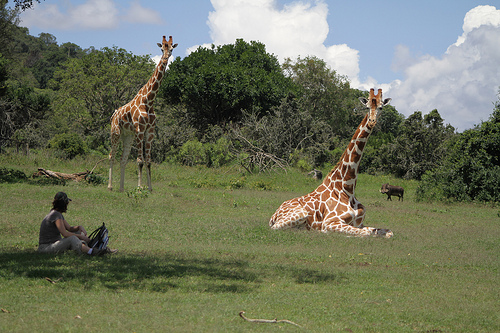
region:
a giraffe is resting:
[263, 83, 398, 265]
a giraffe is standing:
[84, 35, 181, 197]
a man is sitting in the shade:
[31, 182, 112, 271]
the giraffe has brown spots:
[241, 77, 388, 243]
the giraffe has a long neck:
[275, 83, 395, 257]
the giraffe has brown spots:
[96, 31, 181, 193]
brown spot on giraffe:
[358, 128, 369, 141]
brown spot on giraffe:
[349, 148, 359, 163]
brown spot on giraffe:
[342, 164, 357, 179]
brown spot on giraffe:
[330, 166, 342, 180]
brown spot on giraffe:
[318, 184, 326, 191]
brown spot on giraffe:
[331, 189, 341, 201]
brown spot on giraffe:
[339, 190, 349, 202]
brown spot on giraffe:
[333, 203, 348, 214]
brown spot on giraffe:
[313, 195, 320, 207]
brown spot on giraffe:
[140, 104, 152, 114]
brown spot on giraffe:
[358, 130, 370, 140]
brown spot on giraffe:
[347, 140, 356, 152]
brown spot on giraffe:
[342, 182, 356, 191]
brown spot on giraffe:
[315, 184, 325, 194]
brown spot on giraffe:
[129, 108, 139, 123]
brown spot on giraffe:
[139, 92, 149, 103]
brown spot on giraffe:
[128, 105, 136, 116]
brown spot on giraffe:
[114, 118, 119, 128]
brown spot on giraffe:
[304, 202, 317, 209]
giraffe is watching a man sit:
[105, 36, 177, 193]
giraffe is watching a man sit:
[267, 88, 394, 239]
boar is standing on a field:
[378, 184, 403, 198]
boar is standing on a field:
[313, 169, 325, 179]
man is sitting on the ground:
[40, 191, 114, 257]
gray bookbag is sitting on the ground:
[88, 224, 110, 254]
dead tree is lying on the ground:
[33, 166, 94, 183]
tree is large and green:
[157, 41, 297, 115]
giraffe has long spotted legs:
[135, 138, 153, 188]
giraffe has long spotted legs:
[105, 129, 132, 189]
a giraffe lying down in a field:
[271, 85, 391, 238]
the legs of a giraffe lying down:
[271, 211, 390, 239]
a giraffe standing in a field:
[101, 32, 178, 192]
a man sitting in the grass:
[39, 189, 96, 257]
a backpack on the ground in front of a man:
[86, 222, 111, 254]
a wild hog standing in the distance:
[380, 182, 405, 201]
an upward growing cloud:
[185, 0, 366, 85]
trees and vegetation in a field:
[4, 0, 499, 205]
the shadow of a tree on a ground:
[1, 239, 347, 291]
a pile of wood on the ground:
[39, 165, 96, 182]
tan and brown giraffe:
[78, 37, 180, 189]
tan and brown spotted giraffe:
[267, 79, 400, 244]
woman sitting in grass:
[26, 191, 118, 261]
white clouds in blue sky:
[416, 19, 481, 71]